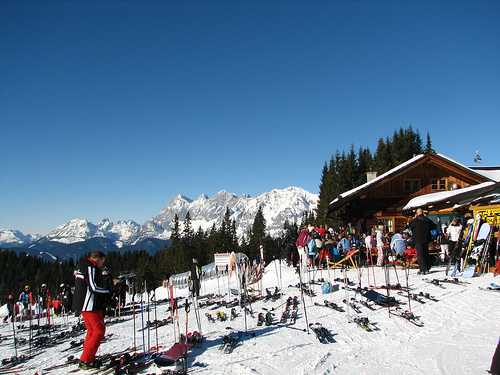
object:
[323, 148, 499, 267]
lodge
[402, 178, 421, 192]
windows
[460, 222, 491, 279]
snowboards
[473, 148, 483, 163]
lift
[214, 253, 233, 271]
sign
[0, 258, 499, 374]
snow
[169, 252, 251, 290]
greenhouse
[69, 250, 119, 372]
man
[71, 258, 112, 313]
coat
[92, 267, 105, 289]
stripes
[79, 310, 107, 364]
pants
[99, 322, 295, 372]
shadow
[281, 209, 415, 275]
crowd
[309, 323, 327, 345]
skis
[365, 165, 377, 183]
chimney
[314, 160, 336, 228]
trees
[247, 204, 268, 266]
trees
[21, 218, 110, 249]
mountains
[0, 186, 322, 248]
snow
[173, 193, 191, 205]
peak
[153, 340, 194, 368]
board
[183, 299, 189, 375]
poles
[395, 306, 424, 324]
skis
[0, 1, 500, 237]
skies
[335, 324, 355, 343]
tracks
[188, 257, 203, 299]
people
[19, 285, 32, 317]
skiers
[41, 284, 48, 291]
helmets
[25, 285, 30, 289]
helmet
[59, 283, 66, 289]
helmet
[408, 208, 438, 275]
man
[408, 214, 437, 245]
coat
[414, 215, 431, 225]
hood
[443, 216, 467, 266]
man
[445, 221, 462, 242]
coat